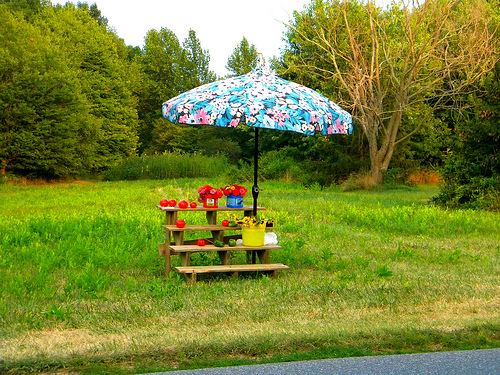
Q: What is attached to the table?
A: Umbrella.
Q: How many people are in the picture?
A: 0.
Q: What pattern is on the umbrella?
A: Flowers.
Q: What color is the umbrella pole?
A: Black.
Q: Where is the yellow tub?
A: On the second step.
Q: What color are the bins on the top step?
A: Red and blue.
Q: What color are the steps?
A: Brown.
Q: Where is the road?
A: At the bottom.